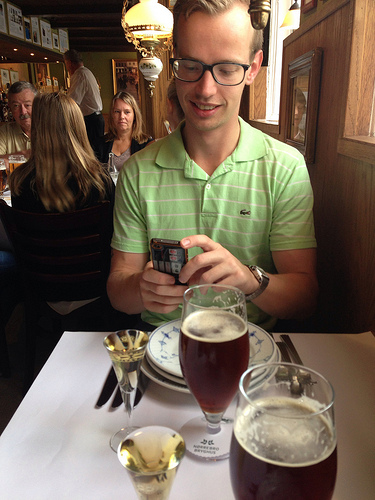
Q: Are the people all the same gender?
A: No, they are both male and female.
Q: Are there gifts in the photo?
A: No, there are no gifts.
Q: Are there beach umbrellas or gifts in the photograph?
A: No, there are no gifts or beach umbrellas.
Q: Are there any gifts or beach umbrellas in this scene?
A: No, there are no gifts or beach umbrellas.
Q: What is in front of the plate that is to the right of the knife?
A: The glass is in front of the plate.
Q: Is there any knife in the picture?
A: Yes, there is a knife.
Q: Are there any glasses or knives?
A: Yes, there is a knife.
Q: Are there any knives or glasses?
A: Yes, there is a knife.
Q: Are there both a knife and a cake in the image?
A: No, there is a knife but no cakes.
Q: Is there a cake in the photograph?
A: No, there are no cakes.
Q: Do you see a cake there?
A: No, there are no cakes.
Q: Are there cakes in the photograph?
A: No, there are no cakes.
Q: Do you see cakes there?
A: No, there are no cakes.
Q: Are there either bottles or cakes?
A: No, there are no cakes or bottles.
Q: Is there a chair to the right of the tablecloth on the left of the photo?
A: No, there is a knife to the right of the tablecloth.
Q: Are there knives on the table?
A: Yes, there is a knife on the table.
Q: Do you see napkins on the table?
A: No, there is a knife on the table.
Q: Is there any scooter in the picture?
A: No, there are no scooters.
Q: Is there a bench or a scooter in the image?
A: No, there are no scooters or benches.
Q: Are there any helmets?
A: No, there are no helmets.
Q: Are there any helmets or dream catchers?
A: No, there are no helmets or dream catchers.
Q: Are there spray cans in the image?
A: No, there are no spray cans.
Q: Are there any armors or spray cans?
A: No, there are no spray cans or armors.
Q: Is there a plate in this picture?
A: Yes, there is a plate.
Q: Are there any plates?
A: Yes, there is a plate.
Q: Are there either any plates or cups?
A: Yes, there is a plate.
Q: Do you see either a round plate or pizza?
A: Yes, there is a round plate.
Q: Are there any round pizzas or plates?
A: Yes, there is a round plate.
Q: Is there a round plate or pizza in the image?
A: Yes, there is a round plate.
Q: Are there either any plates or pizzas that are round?
A: Yes, the plate is round.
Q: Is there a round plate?
A: Yes, there is a round plate.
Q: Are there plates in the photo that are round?
A: Yes, there is a plate that is round.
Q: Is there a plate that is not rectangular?
A: Yes, there is a round plate.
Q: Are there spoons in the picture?
A: No, there are no spoons.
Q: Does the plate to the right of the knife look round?
A: Yes, the plate is round.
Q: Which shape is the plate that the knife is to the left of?
A: The plate is round.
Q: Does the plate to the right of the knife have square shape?
A: No, the plate is round.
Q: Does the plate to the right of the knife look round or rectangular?
A: The plate is round.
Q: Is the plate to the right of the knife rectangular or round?
A: The plate is round.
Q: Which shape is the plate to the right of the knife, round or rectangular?
A: The plate is round.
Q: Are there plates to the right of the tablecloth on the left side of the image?
A: Yes, there is a plate to the right of the tablecloth.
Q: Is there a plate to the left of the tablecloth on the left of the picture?
A: No, the plate is to the right of the tablecloth.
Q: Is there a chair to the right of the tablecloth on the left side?
A: No, there is a plate to the right of the tablecloth.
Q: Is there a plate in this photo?
A: Yes, there is a plate.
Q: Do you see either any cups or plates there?
A: Yes, there is a plate.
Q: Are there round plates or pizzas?
A: Yes, there is a round plate.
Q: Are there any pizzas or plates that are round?
A: Yes, the plate is round.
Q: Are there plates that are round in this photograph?
A: Yes, there is a round plate.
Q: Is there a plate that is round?
A: Yes, there is a plate that is round.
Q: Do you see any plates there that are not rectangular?
A: Yes, there is a round plate.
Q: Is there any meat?
A: No, there is no meat.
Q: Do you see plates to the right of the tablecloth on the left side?
A: Yes, there is a plate to the right of the tablecloth.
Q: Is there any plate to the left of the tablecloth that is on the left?
A: No, the plate is to the right of the tablecloth.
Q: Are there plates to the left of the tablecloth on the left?
A: No, the plate is to the right of the tablecloth.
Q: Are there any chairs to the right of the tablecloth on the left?
A: No, there is a plate to the right of the tablecloth.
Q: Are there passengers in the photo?
A: No, there are no passengers.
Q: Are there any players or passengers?
A: No, there are no passengers or players.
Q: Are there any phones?
A: Yes, there is a phone.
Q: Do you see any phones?
A: Yes, there is a phone.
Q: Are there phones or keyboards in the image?
A: Yes, there is a phone.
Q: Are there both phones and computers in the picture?
A: No, there is a phone but no computers.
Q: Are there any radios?
A: No, there are no radios.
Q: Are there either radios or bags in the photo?
A: No, there are no radios or bags.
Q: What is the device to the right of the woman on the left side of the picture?
A: The device is a phone.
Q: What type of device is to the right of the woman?
A: The device is a phone.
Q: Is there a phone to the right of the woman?
A: Yes, there is a phone to the right of the woman.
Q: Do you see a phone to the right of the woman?
A: Yes, there is a phone to the right of the woman.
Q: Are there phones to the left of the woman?
A: No, the phone is to the right of the woman.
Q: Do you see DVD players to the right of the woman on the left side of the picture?
A: No, there is a phone to the right of the woman.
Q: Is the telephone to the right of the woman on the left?
A: Yes, the telephone is to the right of the woman.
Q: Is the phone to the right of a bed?
A: No, the phone is to the right of the woman.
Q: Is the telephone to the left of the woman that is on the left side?
A: No, the telephone is to the right of the woman.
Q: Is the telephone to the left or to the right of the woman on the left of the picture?
A: The telephone is to the right of the woman.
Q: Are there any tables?
A: Yes, there is a table.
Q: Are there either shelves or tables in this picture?
A: Yes, there is a table.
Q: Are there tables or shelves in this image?
A: Yes, there is a table.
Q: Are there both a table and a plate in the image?
A: Yes, there are both a table and a plate.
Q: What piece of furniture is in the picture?
A: The piece of furniture is a table.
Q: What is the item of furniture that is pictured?
A: The piece of furniture is a table.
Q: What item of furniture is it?
A: The piece of furniture is a table.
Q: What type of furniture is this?
A: This is a table.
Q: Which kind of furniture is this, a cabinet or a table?
A: This is a table.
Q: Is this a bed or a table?
A: This is a table.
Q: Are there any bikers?
A: No, there are no bikers.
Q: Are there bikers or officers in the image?
A: No, there are no bikers or officers.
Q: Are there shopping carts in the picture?
A: No, there are no shopping carts.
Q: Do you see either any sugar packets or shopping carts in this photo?
A: No, there are no shopping carts or sugar packets.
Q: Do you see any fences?
A: No, there are no fences.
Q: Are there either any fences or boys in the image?
A: No, there are no fences or boys.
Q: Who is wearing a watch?
A: The man is wearing a watch.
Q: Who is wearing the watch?
A: The man is wearing a watch.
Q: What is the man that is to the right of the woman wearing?
A: The man is wearing a watch.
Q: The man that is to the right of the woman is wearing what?
A: The man is wearing a watch.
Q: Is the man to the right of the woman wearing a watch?
A: Yes, the man is wearing a watch.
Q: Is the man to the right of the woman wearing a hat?
A: No, the man is wearing a watch.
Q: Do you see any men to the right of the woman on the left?
A: Yes, there is a man to the right of the woman.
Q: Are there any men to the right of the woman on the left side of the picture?
A: Yes, there is a man to the right of the woman.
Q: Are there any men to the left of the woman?
A: No, the man is to the right of the woman.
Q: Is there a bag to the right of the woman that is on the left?
A: No, there is a man to the right of the woman.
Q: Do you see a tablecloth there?
A: Yes, there is a tablecloth.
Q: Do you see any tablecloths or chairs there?
A: Yes, there is a tablecloth.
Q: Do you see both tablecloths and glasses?
A: Yes, there are both a tablecloth and glasses.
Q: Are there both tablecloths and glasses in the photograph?
A: Yes, there are both a tablecloth and glasses.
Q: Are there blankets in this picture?
A: No, there are no blankets.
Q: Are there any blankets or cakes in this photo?
A: No, there are no blankets or cakes.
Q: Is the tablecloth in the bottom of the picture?
A: Yes, the tablecloth is in the bottom of the image.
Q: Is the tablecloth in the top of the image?
A: No, the tablecloth is in the bottom of the image.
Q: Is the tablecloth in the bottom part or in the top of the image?
A: The tablecloth is in the bottom of the image.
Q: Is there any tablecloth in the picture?
A: Yes, there is a tablecloth.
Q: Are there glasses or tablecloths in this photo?
A: Yes, there is a tablecloth.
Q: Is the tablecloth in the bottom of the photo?
A: Yes, the tablecloth is in the bottom of the image.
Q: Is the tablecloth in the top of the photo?
A: No, the tablecloth is in the bottom of the image.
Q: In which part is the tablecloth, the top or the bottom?
A: The tablecloth is in the bottom of the image.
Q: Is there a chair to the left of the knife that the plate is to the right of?
A: No, there is a tablecloth to the left of the knife.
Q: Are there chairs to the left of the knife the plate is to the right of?
A: No, there is a tablecloth to the left of the knife.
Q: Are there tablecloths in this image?
A: Yes, there is a tablecloth.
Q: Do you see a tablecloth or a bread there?
A: Yes, there is a tablecloth.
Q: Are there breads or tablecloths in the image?
A: Yes, there is a tablecloth.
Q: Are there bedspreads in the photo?
A: No, there are no bedspreads.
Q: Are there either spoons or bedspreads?
A: No, there are no bedspreads or spoons.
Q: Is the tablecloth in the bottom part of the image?
A: Yes, the tablecloth is in the bottom of the image.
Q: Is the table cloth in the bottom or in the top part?
A: The table cloth is in the bottom of the image.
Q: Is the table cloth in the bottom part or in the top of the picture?
A: The table cloth is in the bottom of the image.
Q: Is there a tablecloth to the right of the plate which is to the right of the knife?
A: Yes, there is a tablecloth to the right of the plate.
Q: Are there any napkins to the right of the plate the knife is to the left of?
A: No, there is a tablecloth to the right of the plate.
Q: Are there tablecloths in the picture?
A: Yes, there is a tablecloth.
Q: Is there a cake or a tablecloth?
A: Yes, there is a tablecloth.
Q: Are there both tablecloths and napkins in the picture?
A: No, there is a tablecloth but no napkins.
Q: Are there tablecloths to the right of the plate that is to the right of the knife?
A: Yes, there is a tablecloth to the right of the plate.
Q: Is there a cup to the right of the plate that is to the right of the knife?
A: No, there is a tablecloth to the right of the plate.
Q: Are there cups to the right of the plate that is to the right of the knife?
A: No, there is a tablecloth to the right of the plate.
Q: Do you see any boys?
A: No, there are no boys.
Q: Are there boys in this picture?
A: No, there are no boys.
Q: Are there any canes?
A: No, there are no canes.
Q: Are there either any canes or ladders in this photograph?
A: No, there are no canes or ladders.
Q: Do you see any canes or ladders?
A: No, there are no canes or ladders.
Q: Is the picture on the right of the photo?
A: Yes, the picture is on the right of the image.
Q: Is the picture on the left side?
A: No, the picture is on the right of the image.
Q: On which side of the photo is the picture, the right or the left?
A: The picture is on the right of the image.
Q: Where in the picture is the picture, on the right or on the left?
A: The picture is on the right of the image.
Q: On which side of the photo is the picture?
A: The picture is on the right of the image.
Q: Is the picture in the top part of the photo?
A: Yes, the picture is in the top of the image.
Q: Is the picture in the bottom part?
A: No, the picture is in the top of the image.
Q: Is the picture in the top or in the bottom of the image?
A: The picture is in the top of the image.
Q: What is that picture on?
A: The picture is on the wall.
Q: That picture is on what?
A: The picture is on the wall.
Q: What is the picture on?
A: The picture is on the wall.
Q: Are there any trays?
A: No, there are no trays.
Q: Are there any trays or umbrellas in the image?
A: No, there are no trays or umbrellas.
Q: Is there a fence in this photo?
A: No, there are no fences.